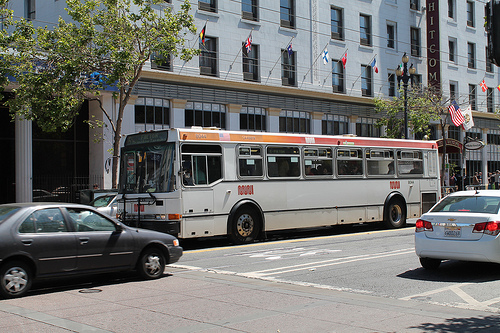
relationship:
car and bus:
[1, 202, 177, 283] [120, 129, 439, 226]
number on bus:
[191, 133, 211, 141] [120, 129, 439, 226]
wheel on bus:
[232, 205, 264, 240] [120, 129, 439, 226]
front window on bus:
[119, 148, 176, 191] [120, 129, 439, 226]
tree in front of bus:
[10, 10, 178, 189] [120, 129, 439, 226]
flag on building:
[195, 28, 216, 42] [3, 3, 499, 149]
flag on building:
[241, 37, 256, 53] [3, 3, 499, 149]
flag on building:
[281, 42, 295, 56] [3, 3, 499, 149]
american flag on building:
[446, 102, 465, 124] [3, 3, 499, 149]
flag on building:
[323, 51, 331, 61] [3, 3, 499, 149]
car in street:
[1, 202, 177, 283] [4, 237, 500, 331]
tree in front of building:
[10, 10, 178, 189] [3, 3, 499, 149]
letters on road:
[258, 244, 317, 270] [4, 237, 500, 331]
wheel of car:
[141, 250, 167, 273] [1, 202, 177, 283]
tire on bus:
[388, 196, 406, 222] [120, 129, 439, 226]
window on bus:
[239, 145, 263, 176] [120, 129, 439, 226]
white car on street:
[421, 192, 499, 258] [4, 237, 500, 331]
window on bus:
[267, 147, 302, 177] [120, 129, 439, 226]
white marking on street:
[217, 260, 369, 290] [4, 237, 500, 331]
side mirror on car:
[111, 224, 127, 231] [1, 202, 177, 283]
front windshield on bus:
[119, 148, 176, 191] [120, 129, 439, 226]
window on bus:
[180, 145, 221, 183] [120, 129, 439, 226]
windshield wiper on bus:
[141, 182, 166, 204] [120, 129, 439, 226]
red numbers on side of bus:
[236, 185, 258, 195] [120, 129, 439, 226]